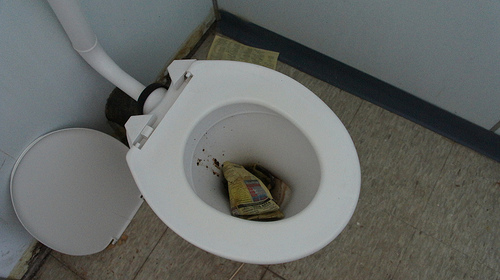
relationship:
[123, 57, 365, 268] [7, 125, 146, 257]
toilet has seat cover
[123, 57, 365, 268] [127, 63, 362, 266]
toilet has seat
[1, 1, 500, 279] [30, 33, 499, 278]
room has tiling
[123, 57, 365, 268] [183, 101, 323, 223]
toilet has bowl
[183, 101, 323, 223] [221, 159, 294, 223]
bowl contains trash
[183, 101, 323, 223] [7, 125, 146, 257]
bowl has seat cover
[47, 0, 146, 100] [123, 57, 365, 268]
pipe connects to toilet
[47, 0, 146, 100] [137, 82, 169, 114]
pipe has connector ring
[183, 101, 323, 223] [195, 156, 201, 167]
bowl has stain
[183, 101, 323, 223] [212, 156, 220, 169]
bowl has stain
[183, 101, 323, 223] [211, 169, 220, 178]
bowl has stain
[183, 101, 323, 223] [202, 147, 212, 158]
bowl has stain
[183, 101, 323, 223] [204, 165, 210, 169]
bowl has stain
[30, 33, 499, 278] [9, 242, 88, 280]
tiling has damage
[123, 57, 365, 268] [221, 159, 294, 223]
toilet contains trash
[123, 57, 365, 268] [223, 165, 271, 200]
toilet has drain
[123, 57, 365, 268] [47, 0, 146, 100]
toilet has pipe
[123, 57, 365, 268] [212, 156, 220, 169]
toilet has stain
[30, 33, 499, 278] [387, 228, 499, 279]
floor has tile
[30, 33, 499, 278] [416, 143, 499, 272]
tiling has tile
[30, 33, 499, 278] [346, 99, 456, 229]
tiling has tile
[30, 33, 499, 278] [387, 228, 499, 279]
tiling has tile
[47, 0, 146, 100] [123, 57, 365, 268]
pipe leads to toilet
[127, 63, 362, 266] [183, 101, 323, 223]
seat connected to bowl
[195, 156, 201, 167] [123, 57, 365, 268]
stain inside toilet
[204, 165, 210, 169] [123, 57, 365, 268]
stain inside toilet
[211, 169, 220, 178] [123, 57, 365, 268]
stain inside toilet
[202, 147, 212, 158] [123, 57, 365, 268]
stain inside toilet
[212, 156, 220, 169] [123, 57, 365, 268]
stain inside toilet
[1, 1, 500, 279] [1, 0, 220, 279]
room has wall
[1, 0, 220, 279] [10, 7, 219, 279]
wall has missing baseboard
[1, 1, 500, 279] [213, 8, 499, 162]
room has base board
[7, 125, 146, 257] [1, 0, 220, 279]
seat cover leaning on wall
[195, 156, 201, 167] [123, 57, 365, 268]
stain on back of toilet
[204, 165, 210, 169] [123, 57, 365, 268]
stain on back of toilet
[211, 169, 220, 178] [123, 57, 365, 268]
stain on back of toilet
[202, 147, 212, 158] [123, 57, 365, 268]
stain on back of toilet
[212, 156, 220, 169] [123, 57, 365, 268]
stain on back of toilet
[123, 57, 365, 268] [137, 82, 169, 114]
toilet has connector ring